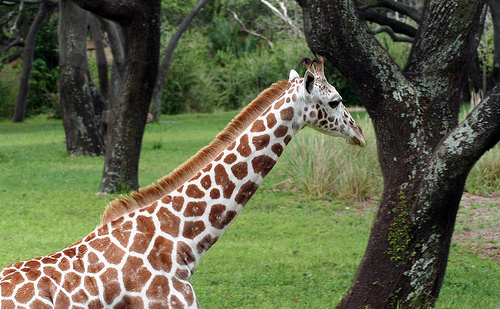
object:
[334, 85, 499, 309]
trunk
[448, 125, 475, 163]
bark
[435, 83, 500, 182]
branch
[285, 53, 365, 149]
head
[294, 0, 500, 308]
tree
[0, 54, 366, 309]
giraffe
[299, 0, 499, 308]
moss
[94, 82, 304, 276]
neck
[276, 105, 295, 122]
spot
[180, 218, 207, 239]
spot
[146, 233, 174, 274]
spot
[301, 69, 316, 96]
ear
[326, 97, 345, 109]
eye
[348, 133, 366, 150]
mouth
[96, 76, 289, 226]
mane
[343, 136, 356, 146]
jaw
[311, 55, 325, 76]
horns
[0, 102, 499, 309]
green grass